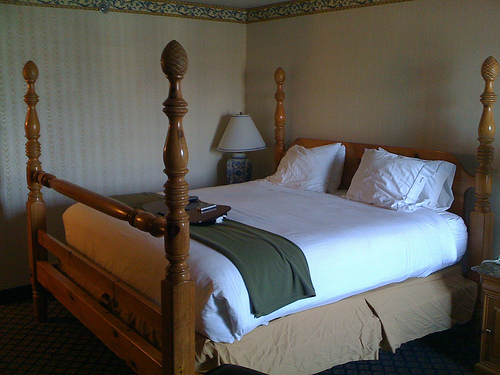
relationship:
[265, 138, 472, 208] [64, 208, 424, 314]
pillow on bed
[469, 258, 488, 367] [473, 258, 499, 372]
edge of table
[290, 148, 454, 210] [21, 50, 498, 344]
four pillows on bed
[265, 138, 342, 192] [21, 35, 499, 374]
pillow on bed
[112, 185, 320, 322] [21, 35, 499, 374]
blanket on bed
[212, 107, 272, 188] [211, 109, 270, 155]
lamp has white top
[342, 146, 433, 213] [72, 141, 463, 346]
pillow on side of bed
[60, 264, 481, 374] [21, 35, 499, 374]
bedsheets on bed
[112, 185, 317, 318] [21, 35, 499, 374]
blanket on bed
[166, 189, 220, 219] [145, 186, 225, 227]
items sitting on tray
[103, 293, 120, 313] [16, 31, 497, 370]
mark on wood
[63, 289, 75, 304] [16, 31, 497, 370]
mark on wood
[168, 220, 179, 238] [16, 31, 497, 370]
mark on wood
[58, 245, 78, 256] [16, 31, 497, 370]
mark on wood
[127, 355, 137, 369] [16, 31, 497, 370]
mark on wood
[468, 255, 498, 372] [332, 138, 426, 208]
night stand next to bed